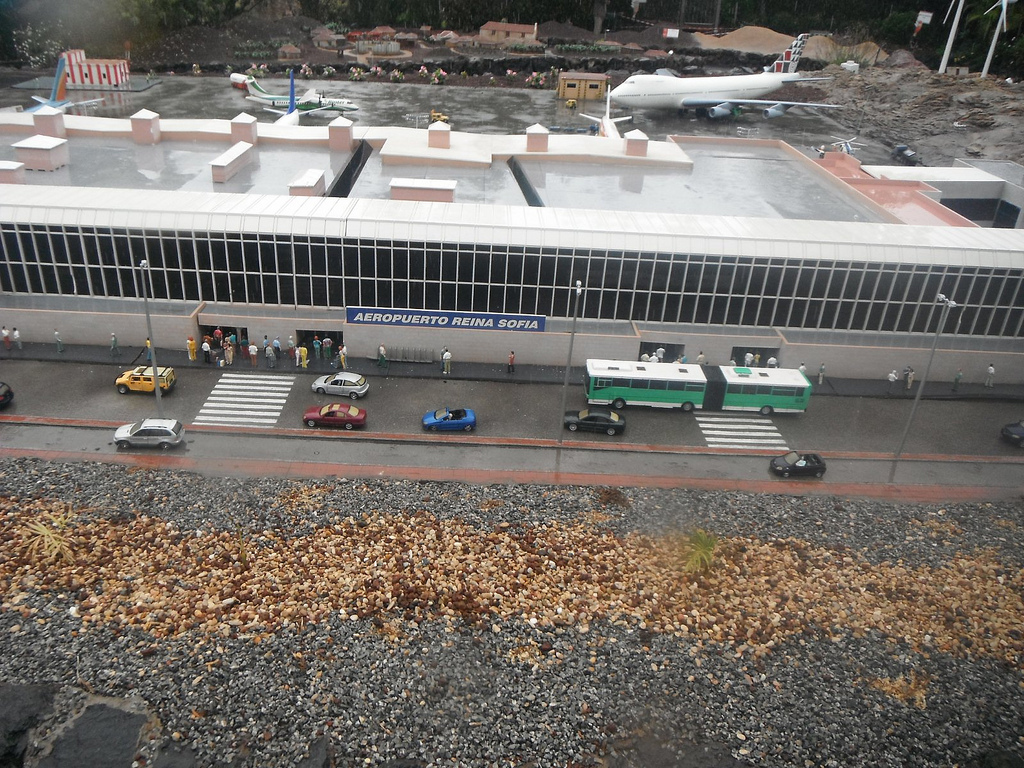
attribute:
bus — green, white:
[579, 357, 815, 418]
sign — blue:
[340, 305, 552, 336]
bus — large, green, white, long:
[579, 350, 815, 424]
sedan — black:
[768, 454, 831, 480]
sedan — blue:
[417, 400, 482, 442]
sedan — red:
[297, 400, 369, 435]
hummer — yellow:
[111, 363, 176, 403]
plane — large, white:
[599, 31, 837, 124]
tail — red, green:
[757, 31, 814, 73]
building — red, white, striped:
[54, 48, 134, 94]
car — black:
[560, 410, 634, 447]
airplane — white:
[605, 27, 848, 121]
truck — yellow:
[113, 359, 176, 399]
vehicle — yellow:
[120, 353, 214, 397]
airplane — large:
[550, 28, 939, 184]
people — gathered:
[166, 320, 415, 409]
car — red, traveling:
[270, 391, 435, 474]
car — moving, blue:
[397, 385, 510, 474]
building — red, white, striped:
[32, 28, 197, 89]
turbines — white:
[907, 13, 1011, 80]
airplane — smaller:
[125, 57, 486, 178]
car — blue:
[386, 392, 497, 470]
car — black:
[555, 392, 676, 462]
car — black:
[743, 430, 912, 530]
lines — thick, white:
[694, 405, 792, 457]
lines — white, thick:
[191, 366, 297, 436]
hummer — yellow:
[111, 358, 178, 397]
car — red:
[301, 399, 369, 434]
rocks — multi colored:
[1, 455, 1023, 765]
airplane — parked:
[608, 34, 831, 128]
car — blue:
[418, 399, 481, 439]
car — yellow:
[109, 360, 174, 400]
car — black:
[768, 448, 829, 485]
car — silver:
[109, 412, 194, 458]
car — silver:
[109, 412, 190, 454]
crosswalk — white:
[191, 369, 300, 428]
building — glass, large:
[1, 99, 1023, 385]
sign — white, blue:
[345, 306, 549, 333]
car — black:
[560, 397, 628, 439]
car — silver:
[310, 369, 373, 398]